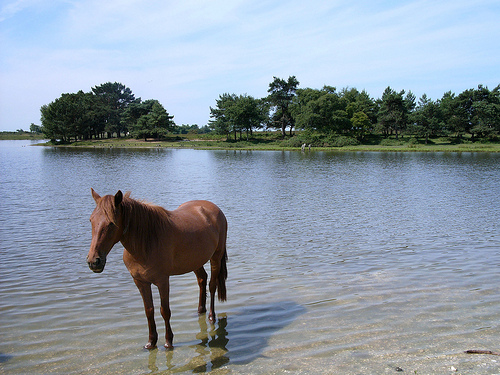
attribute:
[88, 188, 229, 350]
horse — here, brown, standing, motionless, alone, still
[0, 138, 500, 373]
water — calm, dark, clear, beautiful, wavy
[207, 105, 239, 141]
tree — green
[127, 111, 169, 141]
tree — green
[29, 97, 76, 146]
tree — green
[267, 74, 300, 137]
tree — green, dark green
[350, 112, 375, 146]
tree — green, gree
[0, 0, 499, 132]
sky — blue, clear, cloudless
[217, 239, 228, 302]
tail — long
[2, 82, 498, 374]
area — beautiful